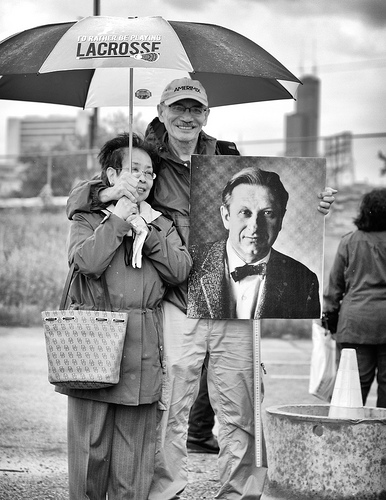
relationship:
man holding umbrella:
[157, 82, 209, 156] [88, 20, 152, 31]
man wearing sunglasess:
[157, 82, 209, 156] [171, 107, 204, 120]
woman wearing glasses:
[132, 148, 155, 204] [133, 167, 157, 179]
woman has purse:
[132, 148, 155, 204] [41, 307, 124, 392]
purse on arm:
[41, 307, 124, 392] [71, 211, 125, 283]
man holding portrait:
[157, 82, 209, 156] [192, 152, 321, 322]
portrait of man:
[192, 152, 321, 322] [220, 171, 282, 266]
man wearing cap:
[157, 82, 209, 156] [156, 80, 211, 104]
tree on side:
[13, 141, 77, 153] [2, 101, 34, 323]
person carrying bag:
[335, 186, 384, 351] [309, 328, 336, 400]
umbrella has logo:
[88, 20, 152, 31] [75, 35, 167, 62]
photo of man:
[192, 152, 321, 322] [220, 171, 282, 266]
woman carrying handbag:
[132, 148, 155, 204] [41, 307, 124, 392]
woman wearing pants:
[132, 148, 155, 204] [67, 407, 157, 499]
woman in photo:
[132, 148, 155, 204] [0, 12, 384, 499]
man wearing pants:
[157, 82, 209, 156] [163, 308, 188, 498]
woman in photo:
[335, 186, 384, 351] [0, 12, 384, 499]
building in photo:
[6, 116, 85, 144] [0, 12, 384, 499]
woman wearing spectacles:
[132, 148, 155, 204] [133, 167, 157, 179]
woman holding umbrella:
[132, 148, 155, 204] [0, 15, 271, 77]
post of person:
[0, 12, 384, 499] [157, 82, 209, 156]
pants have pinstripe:
[67, 407, 157, 499] [77, 404, 78, 499]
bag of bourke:
[41, 307, 124, 392] [78, 338, 83, 344]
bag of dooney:
[41, 307, 124, 392] [75, 336, 82, 343]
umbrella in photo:
[0, 15, 271, 77] [0, 12, 384, 499]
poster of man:
[192, 152, 321, 322] [220, 171, 282, 266]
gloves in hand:
[124, 237, 134, 267] [129, 217, 150, 231]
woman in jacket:
[132, 148, 155, 204] [129, 229, 163, 402]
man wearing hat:
[157, 82, 209, 156] [156, 80, 211, 104]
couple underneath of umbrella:
[88, 89, 208, 202] [0, 15, 271, 77]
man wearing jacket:
[157, 82, 209, 156] [155, 133, 171, 206]